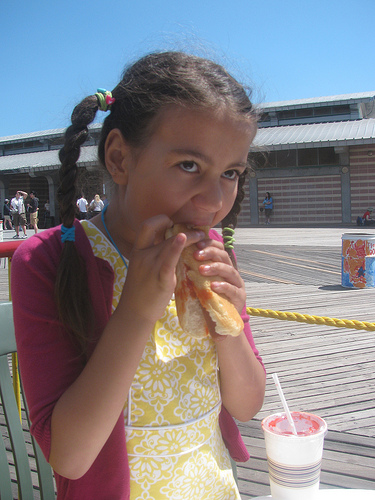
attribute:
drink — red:
[261, 409, 328, 497]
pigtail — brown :
[38, 90, 111, 253]